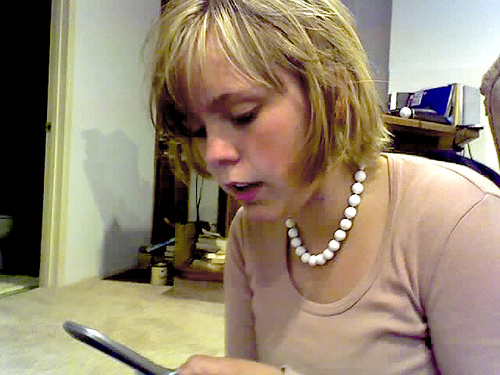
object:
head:
[138, 0, 396, 225]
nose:
[203, 123, 240, 167]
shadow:
[76, 127, 154, 281]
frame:
[38, 0, 73, 288]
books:
[144, 222, 227, 273]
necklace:
[283, 162, 367, 266]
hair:
[135, 1, 397, 192]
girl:
[135, 0, 500, 374]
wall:
[58, 0, 499, 287]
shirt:
[222, 152, 498, 374]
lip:
[224, 185, 265, 200]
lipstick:
[236, 190, 255, 205]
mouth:
[224, 180, 268, 208]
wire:
[193, 174, 205, 220]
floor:
[0, 277, 226, 375]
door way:
[0, 0, 73, 294]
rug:
[103, 267, 174, 286]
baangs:
[140, 0, 324, 104]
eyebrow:
[206, 85, 269, 113]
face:
[166, 31, 326, 224]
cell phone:
[62, 319, 172, 374]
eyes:
[231, 104, 263, 125]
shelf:
[179, 260, 222, 281]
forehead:
[177, 28, 263, 105]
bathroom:
[0, 28, 51, 296]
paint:
[434, 0, 495, 56]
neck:
[294, 158, 354, 241]